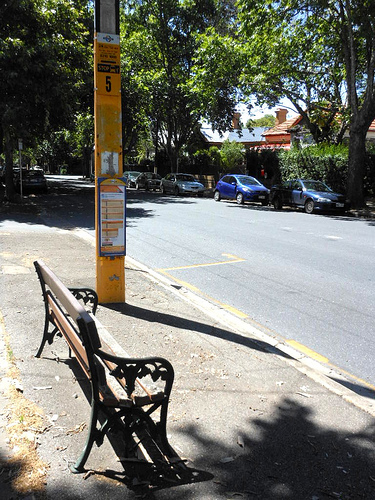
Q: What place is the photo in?
A: It is at the sidewalk.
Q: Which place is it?
A: It is a sidewalk.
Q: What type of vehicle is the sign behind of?
A: The sign is behind the car.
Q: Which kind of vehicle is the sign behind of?
A: The sign is behind the car.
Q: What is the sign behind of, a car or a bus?
A: The sign is behind a car.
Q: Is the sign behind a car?
A: Yes, the sign is behind a car.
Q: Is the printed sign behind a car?
A: Yes, the sign is behind a car.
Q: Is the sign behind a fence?
A: No, the sign is behind a car.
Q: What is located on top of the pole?
A: The sign is on top of the pole.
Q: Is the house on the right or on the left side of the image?
A: The house is on the right of the image.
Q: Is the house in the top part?
A: Yes, the house is in the top of the image.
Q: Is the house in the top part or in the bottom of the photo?
A: The house is in the top of the image.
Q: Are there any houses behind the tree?
A: Yes, there is a house behind the tree.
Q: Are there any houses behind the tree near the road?
A: Yes, there is a house behind the tree.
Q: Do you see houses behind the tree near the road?
A: Yes, there is a house behind the tree.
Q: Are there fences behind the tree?
A: No, there is a house behind the tree.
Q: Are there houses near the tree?
A: Yes, there is a house near the tree.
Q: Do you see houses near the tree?
A: Yes, there is a house near the tree.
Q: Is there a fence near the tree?
A: No, there is a house near the tree.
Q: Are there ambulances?
A: No, there are no ambulances.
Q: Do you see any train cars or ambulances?
A: No, there are no ambulances or train cars.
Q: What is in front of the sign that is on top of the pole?
A: The car is in front of the sign.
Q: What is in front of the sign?
A: The car is in front of the sign.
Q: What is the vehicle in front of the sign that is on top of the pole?
A: The vehicle is a car.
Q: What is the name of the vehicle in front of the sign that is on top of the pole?
A: The vehicle is a car.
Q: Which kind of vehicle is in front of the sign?
A: The vehicle is a car.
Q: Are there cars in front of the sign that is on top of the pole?
A: Yes, there is a car in front of the sign.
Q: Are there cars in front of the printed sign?
A: Yes, there is a car in front of the sign.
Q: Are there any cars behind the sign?
A: No, the car is in front of the sign.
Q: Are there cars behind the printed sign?
A: No, the car is in front of the sign.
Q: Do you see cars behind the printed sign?
A: No, the car is in front of the sign.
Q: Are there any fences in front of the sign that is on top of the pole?
A: No, there is a car in front of the sign.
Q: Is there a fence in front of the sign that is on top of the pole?
A: No, there is a car in front of the sign.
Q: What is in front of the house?
A: The tree is in front of the house.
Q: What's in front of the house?
A: The tree is in front of the house.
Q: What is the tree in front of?
A: The tree is in front of the house.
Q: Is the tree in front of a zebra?
A: No, the tree is in front of a house.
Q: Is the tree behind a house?
A: No, the tree is in front of a house.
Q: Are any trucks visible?
A: No, there are no trucks.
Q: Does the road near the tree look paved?
A: Yes, the road is paved.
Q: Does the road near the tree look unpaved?
A: No, the road is paved.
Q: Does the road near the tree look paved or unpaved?
A: The road is paved.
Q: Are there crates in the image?
A: No, there are no crates.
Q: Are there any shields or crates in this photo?
A: No, there are no crates or shields.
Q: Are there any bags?
A: No, there are no bags.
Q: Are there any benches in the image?
A: Yes, there is a bench.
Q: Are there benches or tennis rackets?
A: Yes, there is a bench.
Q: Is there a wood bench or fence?
A: Yes, there is a wood bench.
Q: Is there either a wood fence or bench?
A: Yes, there is a wood bench.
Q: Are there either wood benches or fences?
A: Yes, there is a wood bench.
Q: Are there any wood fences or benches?
A: Yes, there is a wood bench.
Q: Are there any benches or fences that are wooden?
A: Yes, the bench is wooden.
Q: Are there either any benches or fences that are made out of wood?
A: Yes, the bench is made of wood.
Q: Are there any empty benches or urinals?
A: Yes, there is an empty bench.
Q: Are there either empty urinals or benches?
A: Yes, there is an empty bench.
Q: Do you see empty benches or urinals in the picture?
A: Yes, there is an empty bench.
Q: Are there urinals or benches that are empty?
A: Yes, the bench is empty.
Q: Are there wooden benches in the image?
A: Yes, there is a wood bench.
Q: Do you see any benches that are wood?
A: Yes, there is a wood bench.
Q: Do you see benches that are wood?
A: Yes, there is a wood bench.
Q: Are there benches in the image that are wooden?
A: Yes, there is a bench that is wooden.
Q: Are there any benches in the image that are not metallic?
A: Yes, there is a wooden bench.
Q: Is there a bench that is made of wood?
A: Yes, there is a bench that is made of wood.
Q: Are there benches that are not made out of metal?
A: Yes, there is a bench that is made of wood.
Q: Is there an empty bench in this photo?
A: Yes, there is an empty bench.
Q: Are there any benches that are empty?
A: Yes, there is a bench that is empty.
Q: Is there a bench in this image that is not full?
A: Yes, there is a empty bench.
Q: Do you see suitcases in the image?
A: No, there are no suitcases.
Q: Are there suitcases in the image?
A: No, there are no suitcases.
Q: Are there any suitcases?
A: No, there are no suitcases.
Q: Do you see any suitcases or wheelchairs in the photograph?
A: No, there are no suitcases or wheelchairs.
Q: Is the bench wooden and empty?
A: Yes, the bench is wooden and empty.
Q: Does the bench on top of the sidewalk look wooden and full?
A: No, the bench is wooden but empty.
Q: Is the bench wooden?
A: Yes, the bench is wooden.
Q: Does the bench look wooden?
A: Yes, the bench is wooden.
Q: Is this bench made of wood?
A: Yes, the bench is made of wood.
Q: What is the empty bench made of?
A: The bench is made of wood.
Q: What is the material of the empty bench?
A: The bench is made of wood.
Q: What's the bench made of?
A: The bench is made of wood.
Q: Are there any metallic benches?
A: No, there is a bench but it is wooden.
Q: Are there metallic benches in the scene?
A: No, there is a bench but it is wooden.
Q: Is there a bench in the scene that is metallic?
A: No, there is a bench but it is wooden.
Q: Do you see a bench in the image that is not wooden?
A: No, there is a bench but it is wooden.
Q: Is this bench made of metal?
A: No, the bench is made of wood.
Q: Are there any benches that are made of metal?
A: No, there is a bench but it is made of wood.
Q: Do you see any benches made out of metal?
A: No, there is a bench but it is made of wood.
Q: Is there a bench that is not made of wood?
A: No, there is a bench but it is made of wood.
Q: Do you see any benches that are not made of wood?
A: No, there is a bench but it is made of wood.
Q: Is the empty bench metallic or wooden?
A: The bench is wooden.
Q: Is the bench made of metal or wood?
A: The bench is made of wood.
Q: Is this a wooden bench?
A: Yes, this is a wooden bench.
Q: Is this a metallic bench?
A: No, this is a wooden bench.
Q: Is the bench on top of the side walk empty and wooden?
A: Yes, the bench is empty and wooden.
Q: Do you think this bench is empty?
A: Yes, the bench is empty.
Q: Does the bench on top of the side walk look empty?
A: Yes, the bench is empty.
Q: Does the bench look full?
A: No, the bench is empty.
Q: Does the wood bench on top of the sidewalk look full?
A: No, the bench is empty.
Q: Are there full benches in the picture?
A: No, there is a bench but it is empty.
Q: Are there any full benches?
A: No, there is a bench but it is empty.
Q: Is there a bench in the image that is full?
A: No, there is a bench but it is empty.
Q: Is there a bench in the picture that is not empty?
A: No, there is a bench but it is empty.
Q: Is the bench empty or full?
A: The bench is empty.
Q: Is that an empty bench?
A: Yes, that is an empty bench.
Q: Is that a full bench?
A: No, that is an empty bench.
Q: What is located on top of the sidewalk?
A: The bench is on top of the sidewalk.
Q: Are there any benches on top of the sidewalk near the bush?
A: Yes, there is a bench on top of the sidewalk.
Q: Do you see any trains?
A: No, there are no trains.